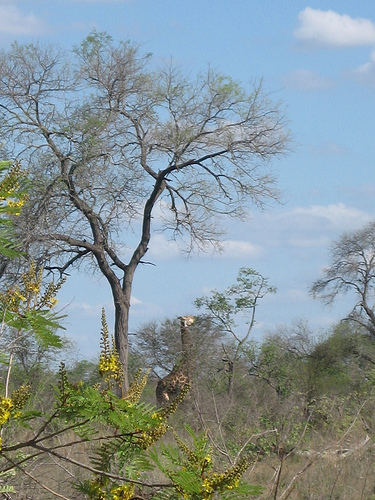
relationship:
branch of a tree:
[137, 122, 206, 182] [41, 172, 158, 396]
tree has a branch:
[41, 172, 158, 396] [137, 122, 206, 182]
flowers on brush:
[93, 305, 117, 390] [0, 310, 375, 500]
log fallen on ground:
[249, 434, 373, 462] [0, 360, 374, 499]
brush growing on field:
[11, 347, 345, 468] [0, 356, 375, 499]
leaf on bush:
[146, 447, 200, 493] [1, 159, 265, 498]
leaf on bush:
[25, 307, 65, 349] [1, 159, 265, 498]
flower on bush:
[96, 306, 124, 393] [1, 159, 265, 498]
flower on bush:
[201, 450, 258, 496] [1, 159, 265, 498]